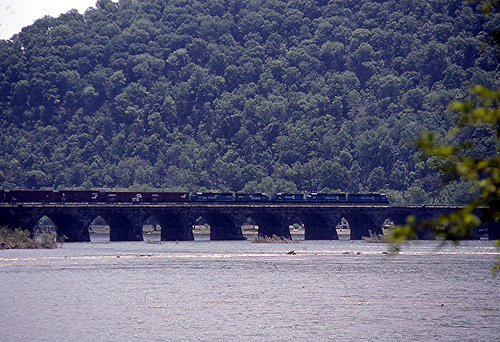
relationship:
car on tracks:
[309, 188, 347, 202] [154, 187, 422, 242]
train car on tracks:
[271, 190, 306, 200] [0, 202, 490, 212]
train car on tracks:
[234, 183, 272, 208] [173, 198, 398, 217]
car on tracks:
[190, 186, 239, 205] [244, 191, 365, 222]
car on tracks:
[139, 182, 190, 204] [396, 195, 487, 217]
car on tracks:
[97, 185, 139, 206] [8, 194, 440, 226]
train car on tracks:
[57, 184, 97, 207] [5, 195, 412, 221]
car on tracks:
[7, 184, 58, 211] [4, 195, 388, 216]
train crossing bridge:
[2, 186, 394, 206] [5, 199, 499, 240]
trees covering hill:
[16, 23, 473, 187] [1, 2, 498, 193]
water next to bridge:
[0, 240, 496, 339] [0, 197, 444, 249]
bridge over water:
[0, 188, 500, 243] [0, 240, 496, 339]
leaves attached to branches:
[376, 78, 498, 256] [384, 74, 499, 252]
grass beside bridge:
[0, 226, 61, 253] [18, 146, 489, 257]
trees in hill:
[43, 47, 315, 178] [1, 2, 498, 193]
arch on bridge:
[134, 207, 180, 249] [0, 186, 495, 246]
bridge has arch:
[5, 199, 499, 240] [36, 213, 60, 244]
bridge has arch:
[5, 199, 499, 240] [88, 213, 110, 243]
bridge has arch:
[5, 199, 499, 240] [144, 215, 164, 243]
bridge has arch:
[5, 199, 499, 240] [236, 216, 257, 238]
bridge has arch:
[5, 199, 499, 240] [288, 216, 308, 240]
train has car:
[0, 189, 392, 206] [145, 185, 190, 201]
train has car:
[0, 189, 392, 206] [93, 186, 135, 201]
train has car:
[0, 189, 392, 206] [53, 183, 95, 202]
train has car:
[0, 189, 392, 206] [7, 186, 56, 206]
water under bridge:
[3, 223, 498, 341] [0, 188, 500, 243]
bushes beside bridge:
[4, 222, 66, 249] [5, 199, 499, 240]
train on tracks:
[0, 189, 392, 206] [2, 200, 498, 211]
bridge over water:
[0, 188, 500, 243] [3, 223, 498, 341]